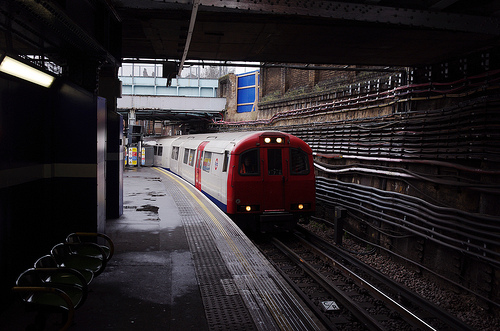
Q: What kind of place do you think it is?
A: It is a station.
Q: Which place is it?
A: It is a station.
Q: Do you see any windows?
A: Yes, there is a window.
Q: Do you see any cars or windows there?
A: Yes, there is a window.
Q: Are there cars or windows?
A: Yes, there is a window.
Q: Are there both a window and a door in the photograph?
A: Yes, there are both a window and a door.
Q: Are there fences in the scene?
A: No, there are no fences.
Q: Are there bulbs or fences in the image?
A: No, there are no fences or bulbs.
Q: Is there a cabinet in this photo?
A: No, there are no cabinets.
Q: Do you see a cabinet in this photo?
A: No, there are no cabinets.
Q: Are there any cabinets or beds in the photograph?
A: No, there are no cabinets or beds.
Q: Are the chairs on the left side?
A: Yes, the chairs are on the left of the image.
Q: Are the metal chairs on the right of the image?
A: No, the chairs are on the left of the image.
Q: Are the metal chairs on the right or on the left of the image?
A: The chairs are on the left of the image.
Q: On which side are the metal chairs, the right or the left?
A: The chairs are on the left of the image.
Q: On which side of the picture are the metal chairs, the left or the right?
A: The chairs are on the left of the image.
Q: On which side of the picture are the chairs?
A: The chairs are on the left of the image.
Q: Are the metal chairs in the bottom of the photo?
A: Yes, the chairs are in the bottom of the image.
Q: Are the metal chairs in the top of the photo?
A: No, the chairs are in the bottom of the image.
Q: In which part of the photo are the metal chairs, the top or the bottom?
A: The chairs are in the bottom of the image.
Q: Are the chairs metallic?
A: Yes, the chairs are metallic.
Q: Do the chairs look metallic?
A: Yes, the chairs are metallic.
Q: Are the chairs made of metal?
A: Yes, the chairs are made of metal.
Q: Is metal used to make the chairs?
A: Yes, the chairs are made of metal.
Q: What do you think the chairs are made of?
A: The chairs are made of metal.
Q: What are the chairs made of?
A: The chairs are made of metal.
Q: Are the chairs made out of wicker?
A: No, the chairs are made of metal.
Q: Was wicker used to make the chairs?
A: No, the chairs are made of metal.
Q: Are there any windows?
A: Yes, there is a window.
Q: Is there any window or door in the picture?
A: Yes, there is a window.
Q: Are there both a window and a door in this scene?
A: Yes, there are both a window and a door.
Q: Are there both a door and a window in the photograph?
A: Yes, there are both a window and a door.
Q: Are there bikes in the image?
A: No, there are no bikes.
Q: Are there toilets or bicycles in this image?
A: No, there are no bicycles or toilets.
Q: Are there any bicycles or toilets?
A: No, there are no bicycles or toilets.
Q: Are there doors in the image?
A: Yes, there is a door.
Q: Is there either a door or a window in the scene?
A: Yes, there is a door.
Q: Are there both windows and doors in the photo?
A: Yes, there are both a door and a window.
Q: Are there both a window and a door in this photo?
A: Yes, there are both a door and a window.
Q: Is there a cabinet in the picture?
A: No, there are no cabinets.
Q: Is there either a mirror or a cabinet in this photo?
A: No, there are no cabinets or mirrors.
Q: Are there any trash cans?
A: No, there are no trash cans.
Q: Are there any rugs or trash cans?
A: No, there are no trash cans or rugs.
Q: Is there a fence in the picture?
A: No, there are no fences.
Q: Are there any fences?
A: No, there are no fences.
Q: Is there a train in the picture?
A: Yes, there is a train.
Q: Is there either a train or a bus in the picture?
A: Yes, there is a train.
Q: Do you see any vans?
A: No, there are no vans.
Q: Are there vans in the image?
A: No, there are no vans.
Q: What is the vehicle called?
A: The vehicle is a train.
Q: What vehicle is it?
A: The vehicle is a train.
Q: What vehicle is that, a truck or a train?
A: This is a train.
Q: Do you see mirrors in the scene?
A: No, there are no mirrors.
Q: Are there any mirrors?
A: No, there are no mirrors.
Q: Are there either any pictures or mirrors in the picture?
A: No, there are no mirrors or pictures.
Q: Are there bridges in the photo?
A: Yes, there is a bridge.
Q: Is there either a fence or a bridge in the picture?
A: Yes, there is a bridge.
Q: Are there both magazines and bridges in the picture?
A: No, there is a bridge but no magazines.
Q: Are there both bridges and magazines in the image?
A: No, there is a bridge but no magazines.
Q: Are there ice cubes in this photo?
A: No, there are no ice cubes.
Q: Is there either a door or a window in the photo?
A: Yes, there are doors.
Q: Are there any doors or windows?
A: Yes, there are doors.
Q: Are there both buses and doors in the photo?
A: No, there are doors but no buses.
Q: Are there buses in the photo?
A: No, there are no buses.